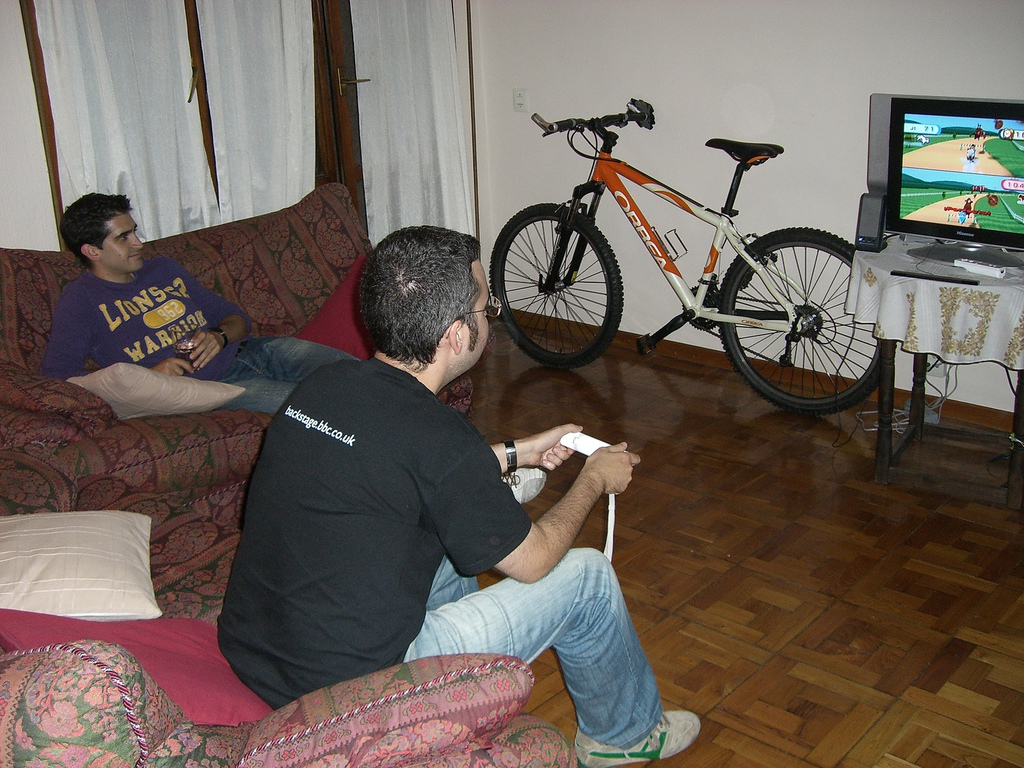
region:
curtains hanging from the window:
[35, 47, 488, 248]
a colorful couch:
[16, 233, 476, 747]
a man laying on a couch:
[21, 199, 355, 414]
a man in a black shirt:
[218, 221, 683, 762]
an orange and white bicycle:
[496, 107, 898, 406]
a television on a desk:
[871, 102, 1023, 239]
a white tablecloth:
[847, 239, 1018, 357]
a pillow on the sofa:
[3, 515, 160, 608]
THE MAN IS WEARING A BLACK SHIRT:
[194, 352, 537, 720]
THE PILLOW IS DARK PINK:
[0, 585, 269, 728]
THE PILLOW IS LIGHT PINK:
[0, 490, 178, 634]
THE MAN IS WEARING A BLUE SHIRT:
[27, 247, 280, 399]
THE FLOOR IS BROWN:
[383, 282, 1014, 764]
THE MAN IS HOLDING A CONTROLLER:
[522, 405, 643, 583]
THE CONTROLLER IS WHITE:
[560, 419, 671, 617]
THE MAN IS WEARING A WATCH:
[484, 428, 530, 504]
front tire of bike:
[441, 152, 648, 380]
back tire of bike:
[663, 200, 920, 495]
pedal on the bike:
[615, 288, 713, 374]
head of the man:
[332, 190, 551, 416]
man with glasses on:
[367, 199, 554, 386]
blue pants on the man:
[367, 518, 725, 765]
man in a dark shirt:
[47, 177, 250, 390]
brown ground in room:
[758, 522, 942, 675]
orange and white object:
[509, 146, 781, 362]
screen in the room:
[767, 70, 1023, 282]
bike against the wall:
[514, 70, 884, 431]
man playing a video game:
[268, 222, 655, 703]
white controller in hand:
[537, 411, 636, 503]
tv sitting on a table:
[865, 88, 1018, 250]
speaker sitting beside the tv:
[846, 176, 892, 275]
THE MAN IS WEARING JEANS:
[367, 523, 688, 742]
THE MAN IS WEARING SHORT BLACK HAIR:
[345, 215, 494, 368]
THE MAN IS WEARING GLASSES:
[460, 292, 502, 332]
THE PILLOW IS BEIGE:
[65, 355, 247, 433]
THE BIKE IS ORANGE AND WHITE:
[478, 96, 913, 445]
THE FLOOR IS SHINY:
[256, 283, 1021, 767]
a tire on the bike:
[728, 215, 874, 384]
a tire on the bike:
[526, 203, 672, 399]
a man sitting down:
[11, 154, 356, 446]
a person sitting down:
[312, 250, 685, 764]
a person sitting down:
[53, 138, 326, 509]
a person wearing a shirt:
[274, 291, 553, 724]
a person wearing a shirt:
[35, 127, 264, 413]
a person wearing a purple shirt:
[31, 215, 294, 403]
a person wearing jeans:
[294, 408, 637, 715]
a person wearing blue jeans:
[400, 435, 717, 765]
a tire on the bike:
[733, 189, 899, 399]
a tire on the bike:
[493, 136, 681, 346]